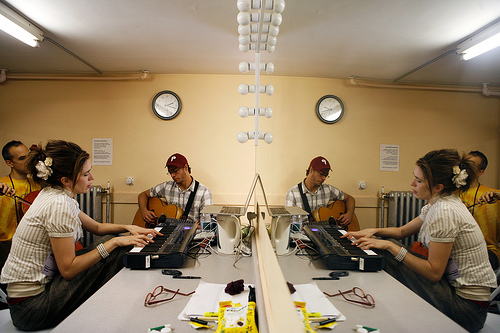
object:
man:
[145, 143, 199, 194]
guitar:
[128, 192, 197, 234]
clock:
[147, 88, 189, 128]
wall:
[106, 73, 223, 154]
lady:
[16, 128, 102, 205]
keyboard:
[122, 201, 195, 283]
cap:
[161, 153, 196, 174]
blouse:
[4, 186, 73, 281]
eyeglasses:
[143, 285, 182, 309]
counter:
[105, 254, 184, 324]